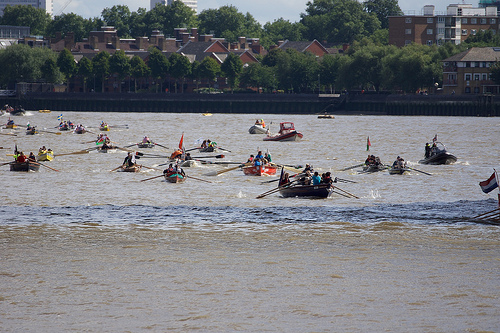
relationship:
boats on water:
[2, 105, 499, 197] [0, 110, 498, 333]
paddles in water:
[331, 185, 358, 199] [0, 110, 498, 333]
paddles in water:
[256, 189, 280, 198] [0, 110, 498, 333]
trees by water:
[3, 28, 500, 93] [0, 110, 498, 333]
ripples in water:
[8, 200, 499, 235] [0, 110, 498, 333]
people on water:
[283, 164, 332, 186] [0, 110, 498, 333]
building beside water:
[444, 46, 500, 95] [0, 110, 498, 333]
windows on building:
[403, 16, 495, 37] [385, 0, 499, 48]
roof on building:
[385, 0, 499, 17] [385, 0, 499, 48]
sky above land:
[46, 1, 479, 30] [2, 93, 499, 115]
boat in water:
[11, 161, 41, 171] [0, 110, 498, 333]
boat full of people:
[277, 183, 333, 197] [283, 164, 332, 186]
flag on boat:
[176, 132, 185, 152] [167, 150, 191, 163]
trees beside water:
[3, 28, 500, 93] [0, 110, 498, 333]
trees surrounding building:
[3, 28, 500, 93] [444, 46, 500, 95]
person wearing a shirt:
[17, 152, 28, 163] [17, 155, 25, 161]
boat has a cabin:
[264, 122, 297, 142] [279, 121, 294, 133]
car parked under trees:
[200, 88, 218, 94] [3, 28, 500, 93]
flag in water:
[479, 166, 499, 194] [0, 110, 498, 333]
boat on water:
[37, 145, 53, 160] [0, 110, 498, 333]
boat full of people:
[239, 164, 277, 175] [246, 150, 273, 165]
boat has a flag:
[167, 150, 191, 163] [176, 132, 185, 152]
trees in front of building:
[3, 28, 500, 93] [444, 46, 500, 95]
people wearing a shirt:
[311, 172, 322, 186] [312, 176, 321, 183]